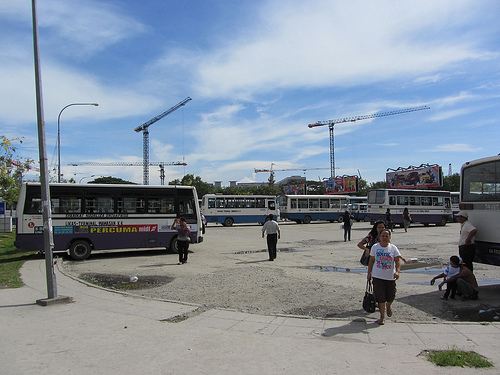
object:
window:
[274, 195, 292, 214]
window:
[461, 160, 500, 200]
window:
[387, 188, 413, 210]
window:
[407, 188, 428, 208]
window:
[425, 192, 454, 210]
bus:
[12, 180, 204, 260]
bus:
[200, 194, 280, 228]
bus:
[277, 194, 353, 225]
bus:
[364, 187, 453, 230]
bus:
[459, 154, 498, 268]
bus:
[272, 194, 287, 216]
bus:
[346, 195, 374, 223]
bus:
[446, 190, 461, 221]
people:
[173, 219, 194, 265]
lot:
[272, 274, 291, 284]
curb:
[102, 272, 344, 335]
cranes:
[306, 105, 431, 194]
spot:
[85, 265, 160, 294]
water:
[395, 254, 440, 282]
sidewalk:
[0, 250, 500, 373]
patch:
[421, 345, 492, 372]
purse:
[359, 294, 372, 314]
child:
[428, 254, 459, 293]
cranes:
[133, 95, 192, 185]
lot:
[189, 272, 261, 303]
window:
[55, 193, 79, 213]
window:
[93, 197, 118, 215]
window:
[283, 194, 317, 215]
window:
[320, 198, 330, 213]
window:
[300, 193, 332, 212]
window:
[398, 193, 415, 206]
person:
[365, 231, 400, 321]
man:
[261, 214, 282, 259]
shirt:
[263, 219, 279, 233]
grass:
[422, 346, 492, 367]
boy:
[437, 263, 477, 298]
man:
[453, 210, 479, 281]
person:
[398, 207, 410, 227]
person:
[381, 206, 393, 226]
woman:
[360, 222, 385, 292]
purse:
[358, 243, 371, 266]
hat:
[455, 209, 470, 218]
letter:
[88, 225, 106, 237]